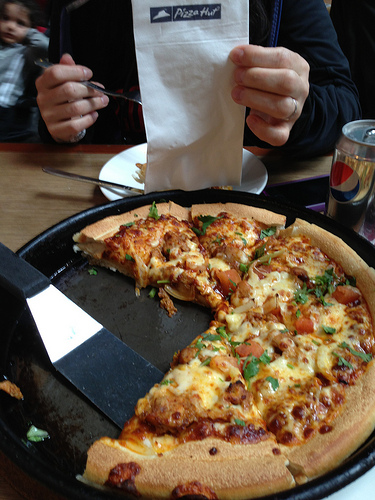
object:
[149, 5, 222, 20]
writing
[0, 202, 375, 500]
serving dish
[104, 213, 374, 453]
cheese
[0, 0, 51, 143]
kid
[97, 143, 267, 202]
plate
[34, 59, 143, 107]
silverware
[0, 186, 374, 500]
pan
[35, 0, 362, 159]
boy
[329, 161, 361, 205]
logo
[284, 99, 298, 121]
band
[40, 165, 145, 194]
siverware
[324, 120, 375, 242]
can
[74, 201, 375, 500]
food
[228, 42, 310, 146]
hand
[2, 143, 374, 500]
table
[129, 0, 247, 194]
napkin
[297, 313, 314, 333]
tomatoes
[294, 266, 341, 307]
herbs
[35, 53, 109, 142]
hand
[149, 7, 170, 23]
logo